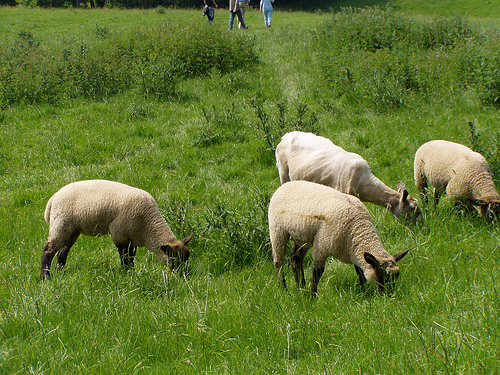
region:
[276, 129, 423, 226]
A white skinny looking sheared sheep.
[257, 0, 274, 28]
A person walking away in light blue jeans and a light blue shirt.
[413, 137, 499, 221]
Grazing sheep to the right of all the rest.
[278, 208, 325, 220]
A dark green mark down a sheeps side.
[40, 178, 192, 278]
A white and black sheep to the left of the others.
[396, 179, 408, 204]
The ears on the skinniest sheep.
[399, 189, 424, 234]
Head of a sheep that is sheared and skinny.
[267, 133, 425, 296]
A sheep with a green smear on it and the skinniest sheep standing together.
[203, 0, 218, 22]
A person in a black shirt with a coat tied around their waist.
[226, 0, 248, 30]
A tall man in jeans wlaking alway with his right arm back.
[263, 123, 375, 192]
Sheep has softer coat of hair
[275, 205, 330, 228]
Green stripe on sheep's side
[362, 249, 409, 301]
Sheep is eating grass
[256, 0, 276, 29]
Person has on blue overalls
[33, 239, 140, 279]
Sheep has dark brown legs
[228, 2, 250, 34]
Person walking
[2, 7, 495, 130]
Field is filled with grass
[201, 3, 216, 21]
Person has jacket wrapped around their waist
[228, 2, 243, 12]
Person has on gray long sleeved shirt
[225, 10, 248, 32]
Person has on blue jeans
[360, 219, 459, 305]
the head of a sheep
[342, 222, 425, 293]
the ears of a sheep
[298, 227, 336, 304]
the leg of a sheep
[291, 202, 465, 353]
a sheep eating grass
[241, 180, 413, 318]
a white sheep in the grass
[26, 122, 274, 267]
a sheep in a field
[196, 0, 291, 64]
people in the background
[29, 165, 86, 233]
the tail of a sheep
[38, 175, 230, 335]
the body of a sheep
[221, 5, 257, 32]
the legs of a man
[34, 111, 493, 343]
four sheep in a field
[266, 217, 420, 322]
a white sheep with a black face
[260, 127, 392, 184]
a sheep with no fur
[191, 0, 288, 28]
four people walking in a field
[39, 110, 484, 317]
four sheep eating grass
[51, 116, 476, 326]
four sheep grazing in a field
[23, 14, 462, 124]
a field of tall green grass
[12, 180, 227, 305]
a sheep eating grass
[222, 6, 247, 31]
a person wearing blue jeans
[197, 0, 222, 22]
a person with a shirt tied around their waist